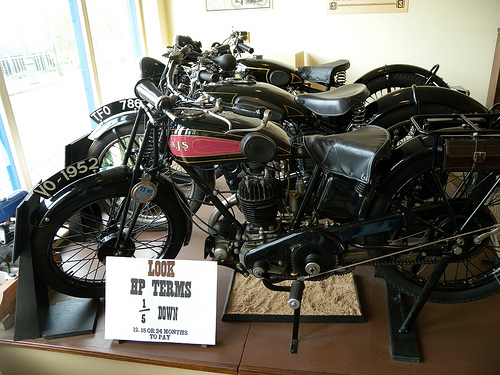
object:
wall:
[166, 0, 500, 108]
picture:
[0, 0, 499, 375]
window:
[0, 0, 100, 197]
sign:
[130, 260, 192, 341]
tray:
[220, 270, 365, 323]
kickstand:
[287, 306, 305, 354]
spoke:
[134, 211, 163, 240]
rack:
[373, 113, 499, 247]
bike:
[31, 44, 500, 354]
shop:
[0, 0, 499, 375]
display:
[0, 0, 490, 368]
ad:
[130, 259, 192, 340]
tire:
[33, 179, 184, 298]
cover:
[29, 165, 193, 247]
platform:
[0, 164, 499, 375]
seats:
[303, 125, 392, 185]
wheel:
[364, 152, 500, 305]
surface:
[12, 44, 499, 354]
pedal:
[287, 280, 305, 309]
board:
[385, 282, 421, 364]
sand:
[225, 264, 361, 315]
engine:
[237, 173, 280, 228]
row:
[64, 44, 500, 232]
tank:
[240, 132, 279, 163]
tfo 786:
[91, 98, 141, 121]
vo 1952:
[34, 158, 98, 198]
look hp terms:
[130, 260, 192, 299]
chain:
[266, 219, 492, 282]